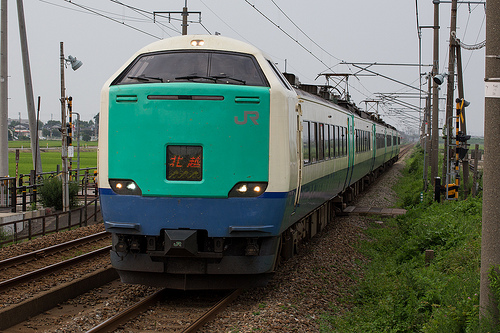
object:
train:
[95, 35, 401, 291]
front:
[94, 34, 303, 291]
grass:
[0, 139, 98, 190]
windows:
[298, 120, 312, 166]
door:
[343, 115, 354, 192]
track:
[0, 229, 240, 332]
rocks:
[387, 168, 400, 176]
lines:
[268, 0, 345, 63]